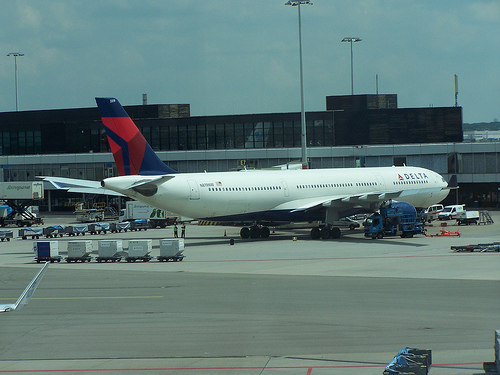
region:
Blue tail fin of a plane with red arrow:
[93, 90, 176, 175]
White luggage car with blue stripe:
[33, 237, 63, 261]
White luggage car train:
[63, 234, 202, 265]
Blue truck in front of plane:
[363, 197, 425, 239]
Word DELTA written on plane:
[400, 170, 432, 180]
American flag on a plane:
[208, 180, 228, 189]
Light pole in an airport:
[283, 1, 311, 171]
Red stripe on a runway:
[2, 357, 494, 374]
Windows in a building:
[169, 120, 324, 143]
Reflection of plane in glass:
[236, 120, 275, 149]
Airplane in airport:
[37, 91, 464, 241]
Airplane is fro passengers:
[33, 88, 472, 250]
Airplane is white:
[29, 76, 473, 243]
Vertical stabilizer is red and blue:
[83, 86, 176, 176]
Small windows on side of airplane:
[200, 178, 386, 195]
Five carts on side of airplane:
[28, 231, 199, 273]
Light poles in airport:
[0, 1, 369, 108]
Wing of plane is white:
[273, 178, 461, 220]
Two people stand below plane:
[164, 214, 193, 241]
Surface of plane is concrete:
[3, 229, 498, 366]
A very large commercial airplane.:
[33, 95, 460, 240]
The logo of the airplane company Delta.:
[397, 170, 432, 180]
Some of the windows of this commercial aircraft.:
[208, 187, 282, 192]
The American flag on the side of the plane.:
[214, 180, 222, 187]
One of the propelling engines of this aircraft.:
[360, 198, 419, 235]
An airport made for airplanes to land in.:
[1, 91, 498, 372]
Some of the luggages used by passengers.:
[380, 345, 433, 373]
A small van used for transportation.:
[436, 203, 466, 222]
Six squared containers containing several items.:
[32, 236, 187, 263]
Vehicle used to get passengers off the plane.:
[0, 178, 46, 227]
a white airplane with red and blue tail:
[29, 91, 466, 248]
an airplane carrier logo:
[391, 171, 428, 182]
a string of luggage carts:
[21, 232, 187, 268]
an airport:
[4, 89, 499, 208]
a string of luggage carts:
[4, 214, 151, 239]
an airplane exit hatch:
[186, 176, 201, 203]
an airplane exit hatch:
[279, 174, 291, 199]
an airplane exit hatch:
[371, 172, 388, 193]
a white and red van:
[436, 201, 470, 221]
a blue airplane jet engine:
[355, 195, 432, 243]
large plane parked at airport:
[83, 8, 459, 258]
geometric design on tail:
[85, 67, 175, 192]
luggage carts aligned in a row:
[15, 232, 200, 262]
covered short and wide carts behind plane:
[0, 207, 160, 237]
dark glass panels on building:
[165, 110, 465, 150]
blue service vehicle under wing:
[347, 182, 424, 247]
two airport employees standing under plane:
[155, 210, 192, 242]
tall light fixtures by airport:
[285, 0, 360, 155]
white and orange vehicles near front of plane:
[417, 192, 467, 223]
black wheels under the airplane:
[228, 205, 363, 250]